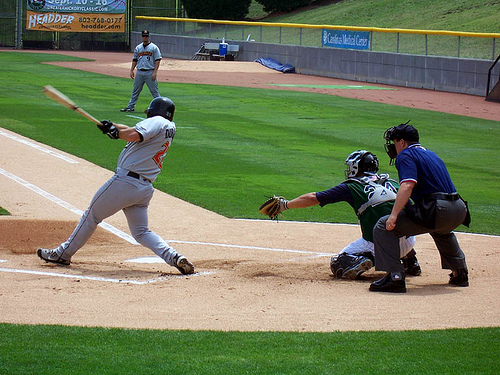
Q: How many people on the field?
A: Four.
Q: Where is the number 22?
A: Jersey.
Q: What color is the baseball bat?
A: Tan.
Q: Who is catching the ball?
A: Catcher.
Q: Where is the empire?
A: Behind the catcher.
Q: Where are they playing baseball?
A: Baseball field.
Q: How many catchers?
A: One.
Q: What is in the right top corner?
A: Stairs.